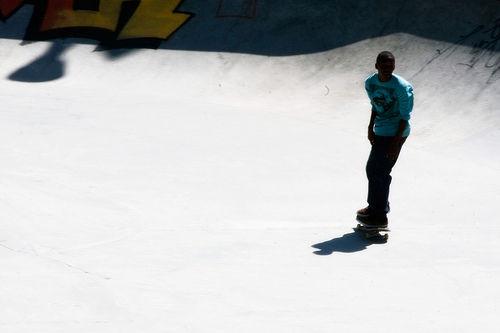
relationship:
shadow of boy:
[313, 222, 389, 255] [354, 48, 416, 230]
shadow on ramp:
[5, 37, 80, 83] [0, 32, 496, 330]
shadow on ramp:
[98, 42, 136, 62] [0, 32, 496, 330]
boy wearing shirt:
[358, 29, 415, 263] [363, 72, 415, 138]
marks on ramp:
[432, 50, 489, 149] [358, 22, 495, 217]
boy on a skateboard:
[354, 48, 416, 230] [356, 214, 393, 240]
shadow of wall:
[10, 4, 492, 59] [133, 50, 244, 98]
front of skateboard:
[342, 168, 373, 283] [364, 197, 393, 246]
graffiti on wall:
[0, 0, 271, 42] [152, 50, 262, 93]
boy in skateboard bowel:
[354, 48, 416, 230] [94, 50, 313, 180]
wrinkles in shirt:
[390, 76, 417, 150] [363, 74, 413, 138]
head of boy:
[366, 50, 395, 114] [325, 56, 449, 244]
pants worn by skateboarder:
[353, 122, 412, 233] [332, 148, 405, 250]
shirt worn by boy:
[363, 72, 415, 141] [354, 48, 416, 230]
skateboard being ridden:
[360, 221, 393, 241] [334, 174, 418, 292]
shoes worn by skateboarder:
[355, 203, 389, 230] [341, 190, 411, 266]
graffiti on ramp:
[0, 0, 197, 52] [179, 50, 351, 102]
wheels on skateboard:
[350, 225, 394, 245] [352, 203, 393, 246]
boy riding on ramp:
[354, 48, 416, 230] [1, 0, 496, 262]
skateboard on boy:
[357, 215, 393, 241] [358, 45, 414, 222]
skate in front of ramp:
[354, 222, 393, 245] [0, 0, 499, 82]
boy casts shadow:
[354, 48, 416, 230] [309, 224, 390, 256]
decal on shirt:
[348, 85, 414, 119] [342, 62, 429, 147]